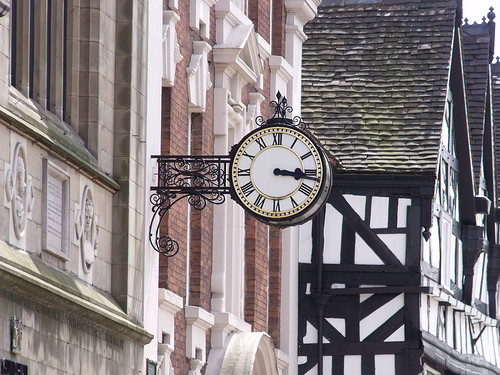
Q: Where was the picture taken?
A: In a city.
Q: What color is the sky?
A: White.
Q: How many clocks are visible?
A: One.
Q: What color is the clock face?
A: White.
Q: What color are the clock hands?
A: Black.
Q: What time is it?
A: 3:16.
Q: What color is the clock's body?
A: Black.